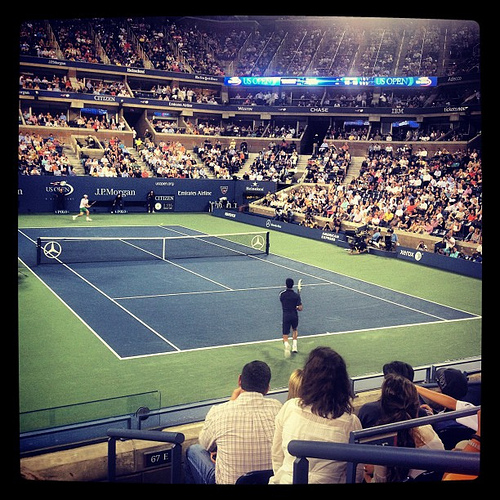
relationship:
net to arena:
[32, 226, 272, 262] [17, 14, 482, 484]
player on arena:
[74, 194, 92, 222] [17, 14, 482, 484]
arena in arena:
[17, 14, 482, 484] [17, 14, 482, 484]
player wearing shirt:
[71, 194, 91, 222] [77, 196, 89, 210]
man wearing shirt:
[280, 278, 301, 361] [279, 290, 303, 306]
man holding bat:
[280, 279, 305, 363] [296, 275, 303, 292]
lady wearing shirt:
[248, 326, 371, 496] [268, 396, 362, 484]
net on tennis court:
[32, 226, 272, 262] [17, 222, 479, 360]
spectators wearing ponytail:
[369, 375, 449, 483] [385, 394, 429, 472]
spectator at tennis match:
[11, 17, 477, 267] [19, 205, 487, 364]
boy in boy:
[144, 188, 159, 215] [147, 189, 156, 214]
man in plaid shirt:
[187, 359, 285, 496] [197, 386, 283, 481]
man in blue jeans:
[187, 359, 285, 496] [234, 466, 274, 486]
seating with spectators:
[22, 22, 482, 266] [210, 132, 460, 264]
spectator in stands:
[11, 17, 482, 266] [29, 15, 484, 247]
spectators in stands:
[229, 353, 467, 474] [29, 15, 484, 247]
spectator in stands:
[11, 17, 482, 266] [198, 358, 483, 475]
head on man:
[234, 357, 271, 399] [205, 363, 284, 496]